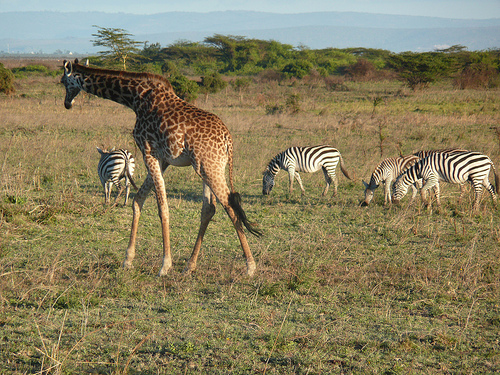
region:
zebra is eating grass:
[261, 143, 353, 199]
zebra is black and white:
[259, 140, 355, 197]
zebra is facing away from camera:
[91, 141, 140, 208]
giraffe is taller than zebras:
[58, 54, 265, 278]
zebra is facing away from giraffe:
[93, 143, 138, 205]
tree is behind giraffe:
[87, 20, 154, 71]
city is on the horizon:
[0, 47, 101, 57]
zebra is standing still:
[260, 143, 354, 196]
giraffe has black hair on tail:
[58, 57, 273, 282]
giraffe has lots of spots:
[56, 58, 268, 278]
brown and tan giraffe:
[59, 58, 263, 278]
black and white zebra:
[260, 145, 351, 200]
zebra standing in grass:
[96, 144, 138, 205]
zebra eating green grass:
[388, 150, 499, 215]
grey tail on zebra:
[338, 154, 354, 182]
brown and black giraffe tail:
[226, 149, 264, 243]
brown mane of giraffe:
[73, 61, 173, 86]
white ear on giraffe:
[83, 59, 91, 66]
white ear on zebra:
[358, 179, 369, 191]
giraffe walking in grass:
[62, 58, 266, 280]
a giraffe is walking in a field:
[55, 59, 264, 282]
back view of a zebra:
[95, 132, 136, 211]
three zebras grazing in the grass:
[256, 139, 495, 219]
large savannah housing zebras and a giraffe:
[0, 78, 497, 373]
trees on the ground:
[0, 39, 495, 92]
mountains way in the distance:
[0, 3, 491, 60]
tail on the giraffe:
[220, 134, 264, 239]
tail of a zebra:
[121, 150, 136, 189]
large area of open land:
[1, 53, 497, 373]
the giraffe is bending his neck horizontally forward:
[53, 58, 268, 273]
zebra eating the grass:
[252, 132, 356, 219]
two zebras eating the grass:
[349, 133, 498, 215]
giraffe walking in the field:
[50, 55, 237, 143]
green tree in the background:
[91, 22, 143, 67]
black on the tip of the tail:
[230, 183, 259, 243]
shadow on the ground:
[168, 184, 200, 208]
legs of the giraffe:
[113, 208, 178, 282]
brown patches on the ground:
[323, 257, 381, 292]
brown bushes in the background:
[330, 55, 397, 85]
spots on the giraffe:
[150, 102, 181, 137]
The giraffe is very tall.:
[56, 56, 262, 281]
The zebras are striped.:
[89, 138, 499, 220]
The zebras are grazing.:
[93, 136, 498, 213]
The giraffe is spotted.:
[56, 57, 263, 278]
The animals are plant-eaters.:
[56, 55, 499, 284]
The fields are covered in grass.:
[1, 30, 499, 374]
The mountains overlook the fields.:
[1, 7, 498, 57]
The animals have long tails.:
[58, 55, 499, 277]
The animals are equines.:
[59, 55, 498, 283]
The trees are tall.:
[1, 30, 498, 105]